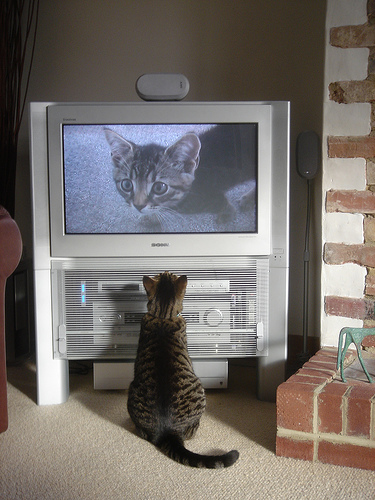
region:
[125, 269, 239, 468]
A cat sitting in front of a tv.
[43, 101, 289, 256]
A grey television that is on.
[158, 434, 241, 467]
A mostly black cat tail.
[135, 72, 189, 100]
A long speaker on the tv.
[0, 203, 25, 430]
The side of a red couch.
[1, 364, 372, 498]
A white carpet.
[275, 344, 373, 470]
The bottom brick area on the carpet.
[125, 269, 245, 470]
cat sitting on the floor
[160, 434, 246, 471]
tail of the cat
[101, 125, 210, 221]
cat on the television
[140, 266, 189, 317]
head of the cat in the room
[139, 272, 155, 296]
left ear of the cat in the room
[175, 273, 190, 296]
right ear of the cat in the room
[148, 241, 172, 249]
brand name of the television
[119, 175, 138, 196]
right eye of the cat on the screen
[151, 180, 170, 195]
left eye of the cat on the screen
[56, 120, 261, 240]
television screen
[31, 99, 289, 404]
shiny silver entertainment center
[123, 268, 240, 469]
black and brown cat sitting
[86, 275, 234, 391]
stereo system behind a grate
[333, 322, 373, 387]
green metal statue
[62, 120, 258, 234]
cat with wide eyes on a screen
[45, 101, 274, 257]
large silver television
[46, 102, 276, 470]
cat watching the television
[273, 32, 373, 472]
brick and white paint fireplace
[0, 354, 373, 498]
light beige carpet on the floor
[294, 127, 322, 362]
speaker attached to a stand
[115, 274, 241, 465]
cat watching television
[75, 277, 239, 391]
stereo system underneath the tv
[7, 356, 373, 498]
beige carpeting in the room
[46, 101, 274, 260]
silver flatscreen television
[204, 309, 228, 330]
knob on the stereo system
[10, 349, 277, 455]
shadows on the carpet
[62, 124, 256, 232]
cat on the tv screen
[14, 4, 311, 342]
wall behind the tv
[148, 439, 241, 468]
tail of the cat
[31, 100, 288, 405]
front of television in stand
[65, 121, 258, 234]
image of cat on tlevision screen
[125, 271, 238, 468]
back of seated cat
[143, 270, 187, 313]
cat head looking up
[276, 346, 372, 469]
corner of red brick surface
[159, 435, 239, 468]
curled tail of cat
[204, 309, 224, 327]
round knob on electronics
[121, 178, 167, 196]
alert eyes of cat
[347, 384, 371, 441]
red brick on fireplace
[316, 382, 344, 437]
red brick on fireplace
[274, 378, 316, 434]
red brick on fireplace